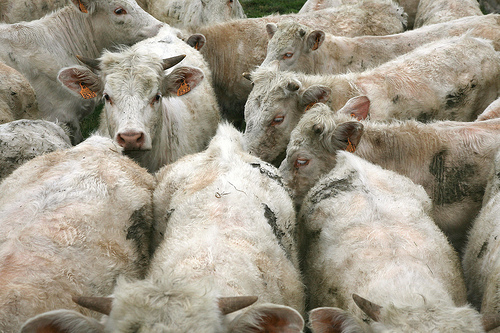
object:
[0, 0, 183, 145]
cow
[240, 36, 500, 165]
cow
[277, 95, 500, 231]
cow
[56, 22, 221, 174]
cow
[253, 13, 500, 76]
cow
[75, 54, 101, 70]
horn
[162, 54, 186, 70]
horn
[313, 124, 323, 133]
horn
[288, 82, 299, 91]
horn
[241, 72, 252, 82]
horn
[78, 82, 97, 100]
ear tag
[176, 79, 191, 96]
ear tag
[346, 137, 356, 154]
ear tag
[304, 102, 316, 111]
ear tag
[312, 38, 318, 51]
ear tag